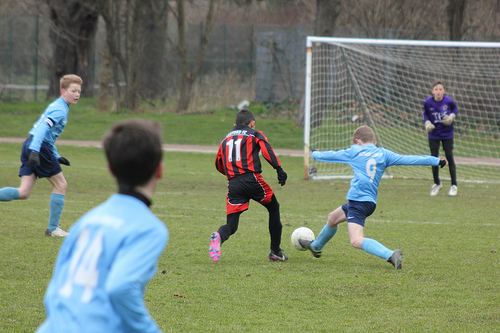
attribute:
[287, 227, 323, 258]
ball — white 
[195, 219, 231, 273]
sole — pink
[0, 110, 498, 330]
grass —  green,  field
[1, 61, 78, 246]
player — of soccer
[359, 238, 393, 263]
blue socks —   for soccer,  blue,  long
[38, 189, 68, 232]
socks —  long,  blue ,   for soccer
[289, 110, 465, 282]
soccer player — in blue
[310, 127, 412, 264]
player — blue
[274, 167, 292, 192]
gloves —  cloth,  black,  warm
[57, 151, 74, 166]
glove —  warm,  black,  cloth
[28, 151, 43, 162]
glove —  warm,  black,  cloth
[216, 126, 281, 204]
uniform —  striped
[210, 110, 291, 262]
player — for soccer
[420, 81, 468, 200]
goalie —  for soccer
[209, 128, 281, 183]
jersey — black 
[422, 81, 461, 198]
soccer player — in blue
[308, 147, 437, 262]
uniform —  blue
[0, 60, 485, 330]
boys —  young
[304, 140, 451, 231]
uniform —  for soccer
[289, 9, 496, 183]
soccer goal —  one,  for soccer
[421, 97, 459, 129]
jersey —  purple